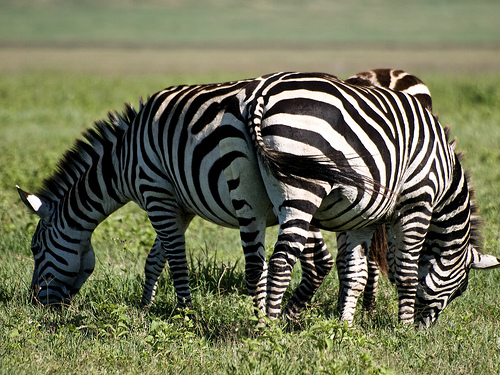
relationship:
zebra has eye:
[14, 78, 280, 312] [31, 246, 40, 255]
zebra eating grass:
[219, 71, 500, 333] [5, 65, 499, 372]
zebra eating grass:
[14, 78, 280, 312] [5, 65, 499, 372]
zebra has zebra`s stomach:
[14, 78, 280, 312] [170, 177, 238, 230]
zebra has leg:
[14, 78, 280, 312] [252, 99, 307, 334]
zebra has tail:
[219, 71, 500, 333] [244, 95, 399, 200]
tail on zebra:
[240, 127, 388, 202] [219, 71, 500, 333]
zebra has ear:
[14, 78, 280, 312] [20, 183, 54, 223]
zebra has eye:
[14, 78, 280, 312] [31, 241, 46, 255]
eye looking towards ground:
[31, 241, 46, 255] [2, 2, 496, 372]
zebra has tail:
[219, 71, 500, 333] [239, 90, 379, 204]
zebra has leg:
[16, 79, 280, 320] [138, 194, 195, 311]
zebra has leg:
[16, 79, 280, 320] [138, 234, 166, 316]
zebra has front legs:
[219, 71, 500, 333] [396, 206, 432, 330]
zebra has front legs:
[219, 71, 500, 333] [365, 231, 382, 318]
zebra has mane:
[35, 94, 272, 308] [34, 113, 141, 194]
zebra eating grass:
[219, 71, 500, 333] [3, 3, 497, 366]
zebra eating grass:
[14, 78, 280, 312] [3, 3, 497, 366]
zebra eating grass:
[341, 68, 433, 285] [3, 3, 497, 366]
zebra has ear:
[219, 71, 500, 333] [466, 244, 499, 271]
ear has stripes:
[466, 244, 499, 271] [469, 245, 481, 264]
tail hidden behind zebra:
[244, 95, 399, 200] [248, 51, 496, 323]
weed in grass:
[162, 294, 210, 349] [16, 50, 89, 110]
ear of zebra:
[13, 186, 54, 226] [63, 45, 439, 316]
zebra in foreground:
[248, 51, 496, 323] [30, 88, 486, 328]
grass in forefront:
[3, 3, 497, 366] [0, 204, 497, 365]